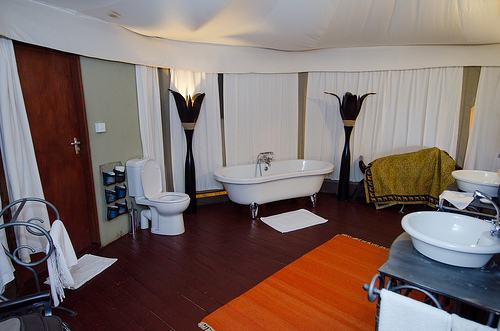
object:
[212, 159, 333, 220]
tub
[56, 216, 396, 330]
floor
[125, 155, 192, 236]
toilet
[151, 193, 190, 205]
toilet seat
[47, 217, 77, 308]
towel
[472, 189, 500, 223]
faucet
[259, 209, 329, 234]
towel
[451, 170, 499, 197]
sink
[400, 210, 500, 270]
sink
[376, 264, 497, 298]
stand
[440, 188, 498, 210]
stand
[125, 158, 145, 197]
porcelain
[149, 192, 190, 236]
tank